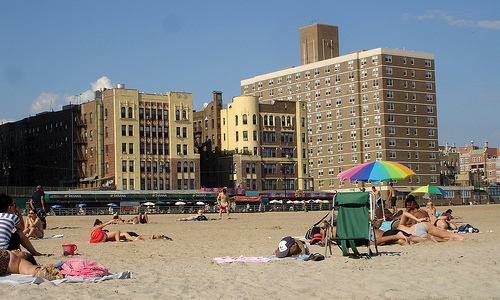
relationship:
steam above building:
[68, 76, 118, 102] [0, 88, 203, 194]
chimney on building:
[91, 87, 110, 101] [0, 88, 203, 194]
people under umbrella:
[369, 181, 404, 209] [336, 158, 422, 184]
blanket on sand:
[64, 258, 112, 280] [174, 271, 238, 299]